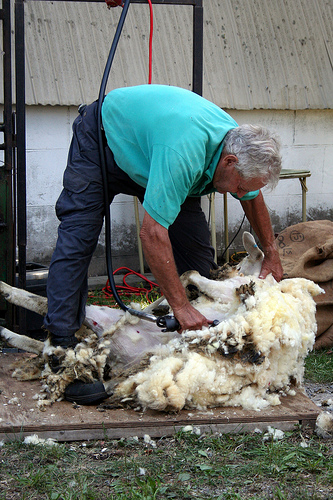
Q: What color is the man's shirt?
A: Aqua.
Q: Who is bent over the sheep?
A: Elderly man.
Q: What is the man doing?
A: Shearing the sheep.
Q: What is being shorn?
A: Sheep.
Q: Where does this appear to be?
A: Farm.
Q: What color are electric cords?
A: Red and black.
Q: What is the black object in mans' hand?
A: Electric shear.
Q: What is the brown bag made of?
A: Burlap.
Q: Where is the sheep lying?
A: Wood platform.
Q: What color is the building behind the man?
A: White.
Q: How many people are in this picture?
A: One.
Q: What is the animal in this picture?
A: Sheep.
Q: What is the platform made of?
A: Wood.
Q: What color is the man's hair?
A: Grey.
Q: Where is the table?
A: Background.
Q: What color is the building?
A: White.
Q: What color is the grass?
A: Green.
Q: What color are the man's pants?
A: Black.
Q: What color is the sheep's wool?
A: White.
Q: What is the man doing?
A: Shearing the sheep.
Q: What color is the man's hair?
A: Grey and white.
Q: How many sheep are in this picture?
A: 1.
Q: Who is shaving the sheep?
A: Man with grey hair.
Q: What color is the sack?
A: Brown.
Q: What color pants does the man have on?
A: Blue.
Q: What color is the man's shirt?
A: Aqua.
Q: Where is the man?
A: Farm.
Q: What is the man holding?
A: Sheep.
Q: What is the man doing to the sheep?
A: Shearing.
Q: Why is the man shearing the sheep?
A: Wool.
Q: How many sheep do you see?
A: One.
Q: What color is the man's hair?
A: Grey.